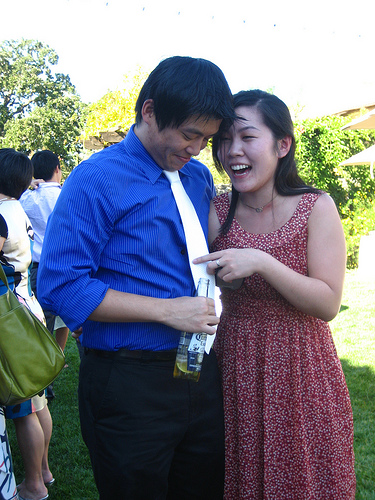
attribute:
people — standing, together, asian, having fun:
[25, 252, 300, 348]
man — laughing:
[99, 95, 218, 277]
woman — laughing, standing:
[218, 108, 333, 294]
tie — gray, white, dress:
[183, 208, 204, 261]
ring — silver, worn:
[215, 259, 222, 269]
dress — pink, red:
[237, 326, 289, 380]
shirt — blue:
[103, 197, 167, 285]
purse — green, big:
[0, 308, 53, 383]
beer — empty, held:
[175, 340, 214, 377]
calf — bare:
[29, 427, 53, 461]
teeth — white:
[222, 160, 251, 173]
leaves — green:
[15, 42, 36, 56]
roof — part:
[256, 82, 365, 133]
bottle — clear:
[184, 319, 209, 356]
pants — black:
[43, 366, 198, 479]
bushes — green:
[346, 199, 369, 226]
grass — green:
[344, 324, 372, 347]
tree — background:
[309, 130, 350, 163]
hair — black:
[151, 63, 219, 100]